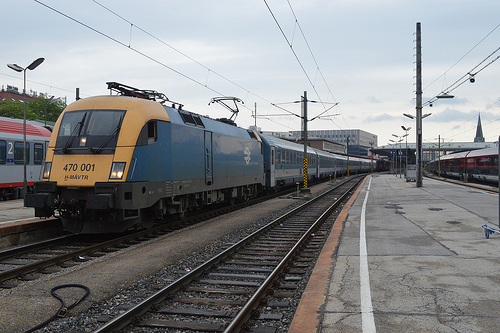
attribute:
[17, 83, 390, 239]
train — black, yellow, electrified, large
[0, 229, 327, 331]
tracks — metal, metalic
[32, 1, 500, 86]
wires — electrical, clear, blue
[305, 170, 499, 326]
platform — grey, concrete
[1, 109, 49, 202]
train — red, grey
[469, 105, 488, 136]
spire — pointed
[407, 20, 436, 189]
pole — tall, wooden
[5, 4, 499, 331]
scene — outdoor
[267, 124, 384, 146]
building — yellow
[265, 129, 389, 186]
cars — blue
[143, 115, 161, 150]
window — open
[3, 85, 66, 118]
foliage — green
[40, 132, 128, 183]
lights — on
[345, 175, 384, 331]
line — white